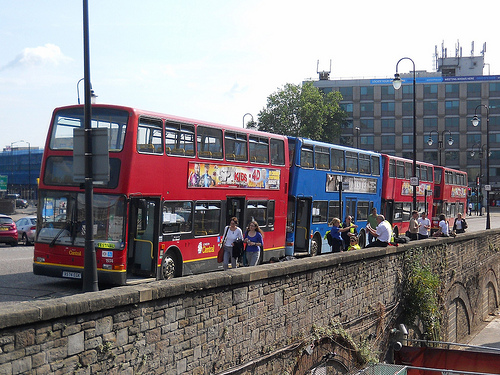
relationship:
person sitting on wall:
[217, 215, 247, 280] [0, 225, 500, 374]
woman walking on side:
[211, 213, 241, 263] [126, 112, 293, 258]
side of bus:
[126, 112, 293, 258] [32, 103, 289, 285]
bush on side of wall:
[388, 258, 446, 348] [150, 293, 497, 373]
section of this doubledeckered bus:
[285, 132, 383, 259] [31, 102, 471, 281]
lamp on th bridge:
[393, 56, 418, 211] [0, 227, 498, 372]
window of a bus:
[135, 115, 164, 153] [32, 103, 289, 285]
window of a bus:
[163, 120, 194, 158] [32, 103, 289, 285]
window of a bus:
[248, 132, 270, 166] [32, 103, 289, 285]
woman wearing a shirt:
[244, 219, 266, 260] [240, 232, 265, 251]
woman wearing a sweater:
[211, 213, 241, 263] [225, 221, 235, 244]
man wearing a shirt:
[416, 208, 431, 238] [415, 217, 434, 232]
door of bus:
[122, 196, 159, 282] [32, 103, 289, 285]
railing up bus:
[110, 229, 155, 268] [32, 103, 289, 285]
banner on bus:
[327, 175, 379, 194] [285, 135, 382, 262]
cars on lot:
[0, 201, 37, 263] [2, 198, 43, 294]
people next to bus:
[231, 208, 464, 269] [63, 93, 460, 257]